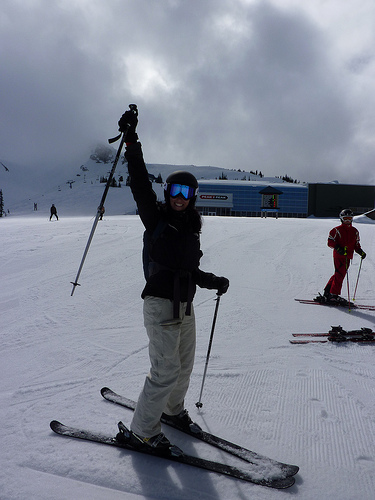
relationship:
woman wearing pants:
[119, 111, 230, 454] [129, 293, 197, 442]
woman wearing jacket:
[119, 111, 230, 454] [123, 138, 212, 304]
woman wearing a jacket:
[119, 111, 230, 454] [123, 138, 212, 304]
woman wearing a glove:
[119, 111, 230, 454] [119, 107, 142, 147]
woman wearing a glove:
[119, 111, 230, 454] [207, 272, 228, 295]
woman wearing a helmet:
[119, 111, 230, 454] [161, 170, 200, 208]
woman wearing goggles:
[119, 111, 230, 454] [162, 180, 198, 201]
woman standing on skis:
[119, 111, 230, 454] [50, 386, 302, 493]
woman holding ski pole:
[119, 111, 230, 454] [68, 103, 139, 299]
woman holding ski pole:
[119, 111, 230, 454] [193, 281, 222, 410]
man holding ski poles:
[322, 207, 366, 303] [339, 246, 361, 302]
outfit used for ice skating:
[323, 226, 361, 298] [291, 200, 374, 323]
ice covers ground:
[4, 214, 370, 498] [1, 213, 374, 497]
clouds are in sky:
[2, 2, 374, 184] [0, 2, 374, 186]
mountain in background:
[0, 162, 293, 217] [3, 150, 372, 213]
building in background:
[196, 180, 308, 215] [3, 150, 372, 213]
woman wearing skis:
[119, 111, 230, 454] [50, 386, 302, 493]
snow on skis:
[225, 445, 299, 488] [50, 386, 302, 493]